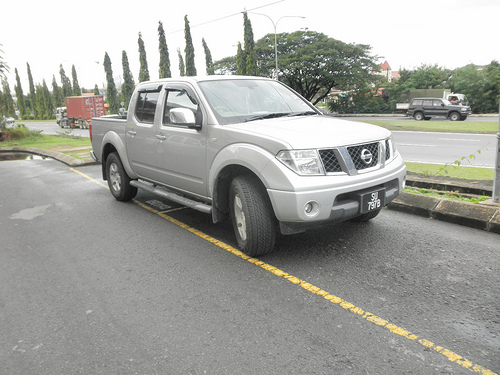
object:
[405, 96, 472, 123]
suv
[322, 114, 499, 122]
sidewalk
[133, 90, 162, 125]
window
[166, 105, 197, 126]
side mirror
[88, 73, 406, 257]
truck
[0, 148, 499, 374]
road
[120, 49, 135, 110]
tree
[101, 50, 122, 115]
tree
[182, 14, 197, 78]
tree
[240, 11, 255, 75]
tree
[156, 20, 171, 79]
tree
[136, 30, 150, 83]
tree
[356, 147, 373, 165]
logo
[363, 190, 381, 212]
plate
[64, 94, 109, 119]
container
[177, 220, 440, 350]
line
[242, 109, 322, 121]
wipers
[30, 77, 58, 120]
plant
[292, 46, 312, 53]
leaf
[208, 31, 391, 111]
plant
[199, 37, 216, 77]
tree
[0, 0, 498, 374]
city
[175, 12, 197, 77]
tree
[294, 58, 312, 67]
leaf